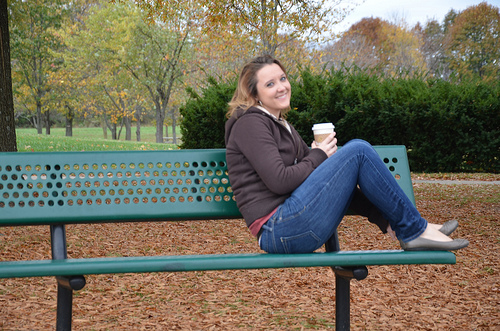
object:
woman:
[224, 53, 469, 253]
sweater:
[224, 103, 329, 228]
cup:
[312, 122, 336, 146]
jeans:
[258, 138, 428, 255]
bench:
[0, 145, 456, 278]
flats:
[399, 220, 469, 252]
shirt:
[249, 205, 280, 238]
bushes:
[177, 64, 500, 177]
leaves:
[107, 277, 320, 329]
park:
[1, 0, 498, 331]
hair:
[225, 54, 292, 120]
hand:
[311, 132, 337, 159]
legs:
[262, 133, 425, 251]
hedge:
[175, 61, 499, 175]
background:
[0, 0, 497, 331]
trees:
[7, 2, 194, 135]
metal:
[57, 226, 62, 233]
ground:
[0, 175, 499, 331]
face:
[257, 63, 292, 110]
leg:
[332, 264, 368, 331]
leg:
[51, 277, 86, 330]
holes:
[87, 172, 95, 180]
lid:
[312, 122, 336, 135]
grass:
[10, 126, 181, 152]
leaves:
[132, 143, 155, 152]